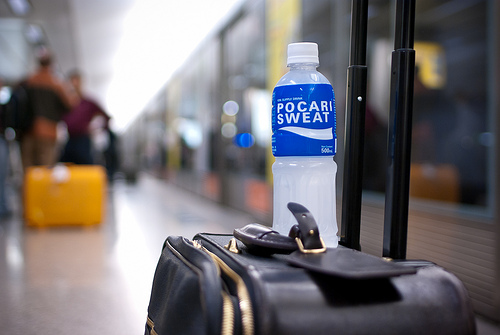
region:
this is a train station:
[8, 26, 415, 271]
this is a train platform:
[79, 89, 244, 268]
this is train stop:
[141, 156, 278, 311]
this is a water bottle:
[229, 50, 345, 202]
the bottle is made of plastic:
[224, 18, 322, 203]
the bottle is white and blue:
[283, 36, 323, 181]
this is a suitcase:
[144, 211, 306, 318]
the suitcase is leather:
[140, 228, 357, 333]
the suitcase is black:
[201, 243, 353, 328]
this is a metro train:
[142, 31, 297, 176]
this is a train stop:
[35, 25, 389, 290]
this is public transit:
[30, 17, 473, 327]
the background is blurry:
[13, 61, 163, 206]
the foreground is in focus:
[118, 98, 292, 295]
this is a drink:
[130, 70, 412, 255]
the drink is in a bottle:
[262, 66, 397, 273]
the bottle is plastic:
[204, 20, 346, 252]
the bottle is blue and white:
[239, 34, 343, 218]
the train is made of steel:
[140, 34, 257, 187]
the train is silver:
[155, 55, 283, 228]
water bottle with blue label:
[270, 40, 340, 241]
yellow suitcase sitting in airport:
[23, 161, 110, 235]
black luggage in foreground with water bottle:
[146, 213, 473, 331]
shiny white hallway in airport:
[3, 168, 274, 328]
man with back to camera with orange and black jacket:
[6, 45, 76, 172]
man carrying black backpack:
[0, 49, 72, 171]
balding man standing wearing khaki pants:
[2, 45, 77, 173]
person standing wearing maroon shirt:
[62, 67, 112, 164]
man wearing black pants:
[51, 66, 116, 161]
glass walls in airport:
[116, 0, 496, 321]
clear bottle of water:
[263, 33, 350, 245]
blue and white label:
[266, 78, 341, 154]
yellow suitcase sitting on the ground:
[16, 162, 117, 229]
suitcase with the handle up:
[123, 0, 481, 334]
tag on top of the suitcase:
[277, 238, 424, 294]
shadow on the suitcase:
[306, 267, 410, 312]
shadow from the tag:
[304, 262, 411, 310]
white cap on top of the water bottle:
[283, 38, 328, 68]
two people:
[13, 45, 140, 232]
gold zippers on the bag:
[197, 242, 266, 334]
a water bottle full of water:
[264, 39, 348, 246]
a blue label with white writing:
[267, 83, 337, 157]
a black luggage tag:
[290, 237, 412, 283]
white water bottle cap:
[284, 36, 321, 67]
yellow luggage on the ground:
[23, 160, 106, 235]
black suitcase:
[133, 225, 475, 332]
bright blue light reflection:
[234, 125, 252, 150]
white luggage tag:
[52, 162, 67, 181]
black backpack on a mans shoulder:
[2, 81, 36, 136]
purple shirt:
[62, 95, 106, 131]